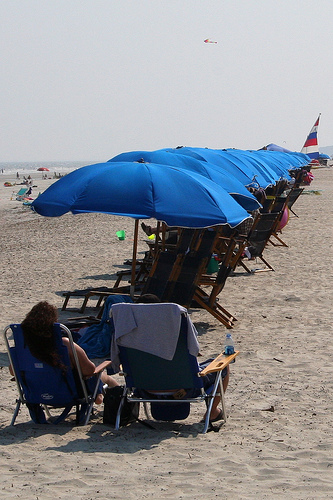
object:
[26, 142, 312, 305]
row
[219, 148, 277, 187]
umbrella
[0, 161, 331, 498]
beach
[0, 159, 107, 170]
ocean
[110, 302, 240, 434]
beach chair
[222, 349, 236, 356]
cup holder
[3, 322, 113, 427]
beach chair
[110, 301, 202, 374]
shirt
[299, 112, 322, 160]
sail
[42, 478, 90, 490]
track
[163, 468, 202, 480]
track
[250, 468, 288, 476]
track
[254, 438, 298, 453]
track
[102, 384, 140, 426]
bag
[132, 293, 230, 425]
person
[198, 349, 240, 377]
arm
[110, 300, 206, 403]
back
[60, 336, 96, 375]
arm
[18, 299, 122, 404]
person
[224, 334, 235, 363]
bottle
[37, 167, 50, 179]
umbrella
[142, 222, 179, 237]
person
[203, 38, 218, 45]
plane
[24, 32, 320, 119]
sky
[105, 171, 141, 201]
blue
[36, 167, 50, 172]
red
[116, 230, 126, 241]
bucket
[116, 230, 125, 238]
green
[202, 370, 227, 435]
metal legs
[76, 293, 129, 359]
wooden chairs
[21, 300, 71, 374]
brunette hair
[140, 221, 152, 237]
foot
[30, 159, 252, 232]
blue umbrellas